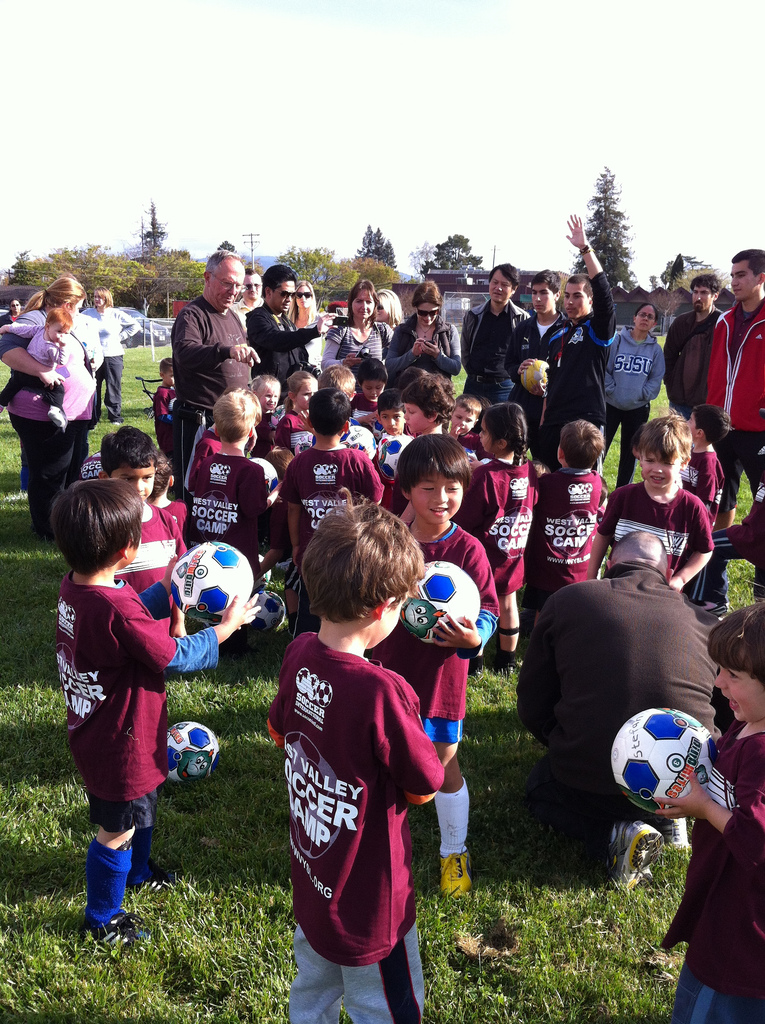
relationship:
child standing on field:
[273, 492, 448, 1020] [3, 352, 763, 1021]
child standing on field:
[46, 482, 258, 951] [1, 353, 755, 951]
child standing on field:
[654, 600, 764, 1021] [3, 352, 763, 1021]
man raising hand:
[537, 223, 616, 472] [561, 212, 591, 249]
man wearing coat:
[695, 247, 763, 585] [708, 296, 763, 440]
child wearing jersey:
[273, 492, 448, 1020] [264, 625, 447, 967]